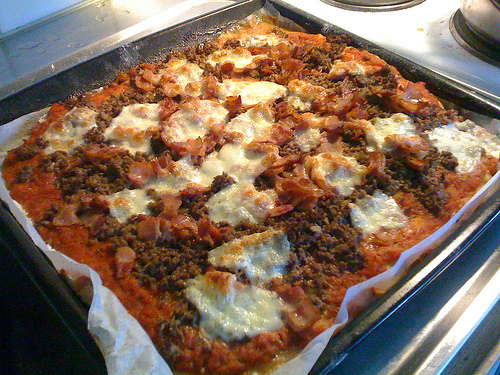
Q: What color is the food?
A: Brown, red and white.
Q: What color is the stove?
A: Silver.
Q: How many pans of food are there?
A: One.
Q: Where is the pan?
A: On top of the stove.